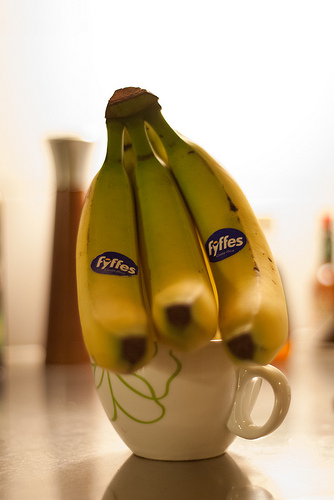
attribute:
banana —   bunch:
[178, 146, 294, 357]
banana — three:
[75, 112, 154, 372]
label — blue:
[201, 228, 245, 263]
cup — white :
[88, 338, 289, 460]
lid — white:
[47, 135, 93, 187]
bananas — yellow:
[136, 152, 245, 211]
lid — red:
[322, 216, 331, 229]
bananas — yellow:
[64, 104, 299, 377]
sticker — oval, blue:
[89, 249, 139, 278]